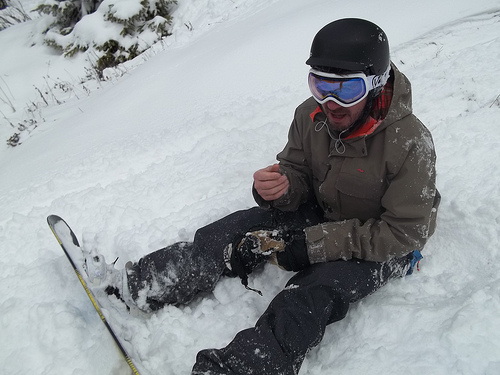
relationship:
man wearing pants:
[206, 31, 493, 322] [176, 200, 433, 367]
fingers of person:
[253, 163, 290, 201] [75, 14, 445, 371]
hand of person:
[206, 154, 316, 274] [75, 14, 445, 371]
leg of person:
[209, 251, 399, 372] [75, 14, 445, 371]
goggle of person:
[307, 70, 391, 107] [75, 14, 445, 371]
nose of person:
[325, 103, 344, 118] [75, 14, 445, 371]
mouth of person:
[325, 107, 356, 127] [75, 14, 445, 371]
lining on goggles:
[302, 65, 369, 83] [288, 51, 408, 110]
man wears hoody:
[125, 16, 437, 375] [250, 59, 441, 271]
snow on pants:
[196, 307, 246, 334] [109, 184, 426, 372]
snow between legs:
[196, 307, 246, 334] [79, 207, 360, 368]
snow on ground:
[196, 307, 246, 334] [2, 2, 497, 374]